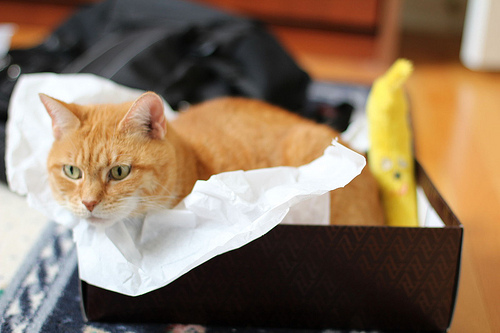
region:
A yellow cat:
[12, 68, 417, 258]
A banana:
[329, 49, 469, 266]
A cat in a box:
[21, 68, 426, 312]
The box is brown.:
[30, 201, 497, 326]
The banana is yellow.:
[347, 47, 447, 252]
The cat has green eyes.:
[12, 62, 229, 249]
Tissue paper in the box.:
[10, 58, 357, 289]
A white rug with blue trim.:
[2, 197, 89, 330]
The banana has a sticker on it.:
[348, 39, 455, 251]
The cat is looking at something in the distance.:
[17, 65, 214, 243]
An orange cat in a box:
[18, 63, 397, 305]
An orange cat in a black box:
[30, 86, 398, 317]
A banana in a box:
[338, 71, 458, 260]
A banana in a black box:
[339, 66, 471, 314]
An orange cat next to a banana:
[33, 53, 462, 236]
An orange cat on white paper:
[10, 64, 299, 229]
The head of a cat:
[18, 83, 198, 227]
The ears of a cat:
[37, 75, 181, 139]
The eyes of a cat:
[48, 155, 147, 184]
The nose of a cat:
[75, 186, 112, 210]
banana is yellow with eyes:
[361, 60, 428, 237]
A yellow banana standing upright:
[371, 46, 431, 231]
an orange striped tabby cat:
[35, 76, 335, 233]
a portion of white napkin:
[139, 125, 384, 299]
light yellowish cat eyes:
[52, 149, 136, 191]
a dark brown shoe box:
[214, 173, 496, 331]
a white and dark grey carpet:
[1, 190, 86, 331]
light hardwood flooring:
[411, 21, 498, 220]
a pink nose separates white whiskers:
[29, 181, 164, 232]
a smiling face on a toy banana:
[351, 124, 424, 219]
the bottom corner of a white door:
[438, 4, 495, 84]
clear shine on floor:
[450, 92, 479, 166]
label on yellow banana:
[383, 154, 406, 177]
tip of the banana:
[390, 49, 416, 76]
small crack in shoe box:
[438, 208, 475, 258]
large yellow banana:
[364, 53, 436, 212]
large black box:
[93, 41, 483, 305]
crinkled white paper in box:
[76, 193, 278, 295]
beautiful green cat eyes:
[99, 145, 153, 189]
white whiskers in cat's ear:
[105, 85, 179, 147]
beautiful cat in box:
[18, 50, 399, 269]